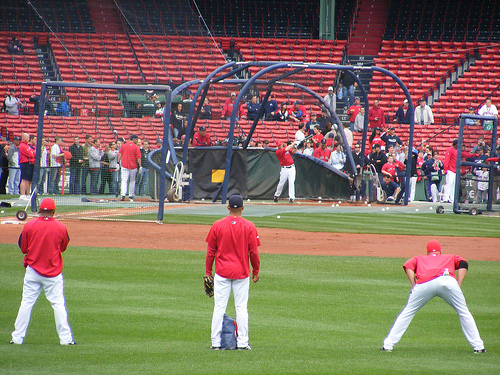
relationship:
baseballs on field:
[196, 195, 206, 205] [0, 196, 498, 373]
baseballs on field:
[243, 196, 250, 205] [0, 196, 498, 373]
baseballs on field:
[274, 212, 281, 221] [0, 196, 498, 373]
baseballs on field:
[316, 197, 323, 206] [0, 196, 498, 373]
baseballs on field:
[337, 198, 342, 205] [0, 196, 498, 373]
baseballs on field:
[335, 200, 343, 207] [0, 196, 498, 373]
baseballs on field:
[328, 201, 334, 209] [0, 196, 498, 373]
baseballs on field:
[361, 197, 368, 205] [0, 196, 498, 373]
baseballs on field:
[365, 202, 372, 209] [0, 196, 498, 373]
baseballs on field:
[384, 202, 391, 209] [0, 196, 498, 373]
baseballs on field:
[379, 205, 385, 214] [0, 196, 498, 373]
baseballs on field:
[428, 205, 433, 213] [0, 196, 498, 373]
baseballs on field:
[412, 206, 420, 215] [0, 196, 498, 373]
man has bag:
[201, 195, 261, 352] [218, 311, 239, 351]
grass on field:
[259, 254, 367, 366] [0, 196, 498, 373]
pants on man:
[387, 273, 488, 348] [377, 236, 487, 354]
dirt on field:
[4, 212, 496, 264] [12, 189, 497, 351]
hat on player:
[228, 192, 242, 207] [202, 192, 262, 347]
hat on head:
[228, 192, 242, 207] [228, 196, 243, 216]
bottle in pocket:
[442, 267, 451, 276] [439, 273, 453, 288]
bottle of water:
[442, 267, 451, 276] [444, 265, 449, 293]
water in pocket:
[444, 265, 449, 293] [439, 273, 453, 288]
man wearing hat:
[201, 195, 261, 352] [423, 238, 441, 254]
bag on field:
[218, 311, 239, 351] [0, 192, 498, 374]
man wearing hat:
[8, 196, 80, 345] [37, 196, 59, 212]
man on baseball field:
[8, 196, 80, 345] [0, 192, 500, 372]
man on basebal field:
[8, 196, 80, 345] [1, 192, 498, 371]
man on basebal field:
[201, 195, 261, 352] [1, 192, 498, 371]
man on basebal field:
[377, 236, 487, 354] [1, 192, 498, 371]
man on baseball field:
[382, 241, 483, 355] [9, 155, 494, 370]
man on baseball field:
[201, 195, 261, 352] [9, 155, 494, 370]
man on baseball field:
[8, 196, 80, 345] [9, 155, 494, 370]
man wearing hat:
[377, 236, 487, 354] [420, 229, 443, 254]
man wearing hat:
[201, 195, 261, 352] [222, 189, 245, 212]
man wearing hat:
[8, 196, 80, 345] [37, 194, 55, 214]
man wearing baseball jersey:
[8, 204, 72, 348] [18, 216, 71, 280]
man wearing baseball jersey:
[198, 195, 261, 352] [203, 215, 265, 279]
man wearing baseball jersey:
[8, 196, 80, 345] [18, 212, 68, 277]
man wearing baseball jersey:
[377, 236, 487, 354] [398, 239, 462, 283]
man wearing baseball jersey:
[382, 241, 483, 355] [400, 252, 470, 284]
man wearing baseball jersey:
[201, 195, 261, 352] [203, 215, 261, 279]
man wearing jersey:
[8, 196, 80, 345] [11, 214, 71, 345]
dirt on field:
[0, 198, 496, 264] [0, 196, 498, 373]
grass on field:
[0, 194, 499, 375] [0, 196, 498, 373]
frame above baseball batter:
[173, 56, 414, 206] [270, 132, 312, 204]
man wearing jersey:
[377, 236, 487, 354] [271, 143, 301, 167]